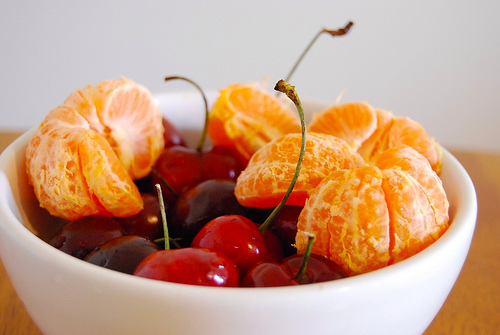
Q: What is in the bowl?
A: Fruit.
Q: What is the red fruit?
A: Cherries.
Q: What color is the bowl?
A: White.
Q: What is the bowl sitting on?
A: Table.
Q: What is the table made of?
A: Wood.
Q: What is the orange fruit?
A: Tangerine.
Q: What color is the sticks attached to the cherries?
A: Green.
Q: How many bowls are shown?
A: 1.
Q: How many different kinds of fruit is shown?
A: 2.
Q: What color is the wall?
A: White.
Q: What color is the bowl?
A: White.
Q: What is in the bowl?
A: Fruit.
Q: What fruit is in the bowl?
A: Oranges and cherries.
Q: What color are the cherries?
A: Red.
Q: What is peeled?
A: Oranges.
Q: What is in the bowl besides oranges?
A: Cherries.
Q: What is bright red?
A: Cherries.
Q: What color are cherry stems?
A: Green.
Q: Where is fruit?
A: In a bowl.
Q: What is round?
A: Bowl.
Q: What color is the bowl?
A: White.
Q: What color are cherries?
A: Red.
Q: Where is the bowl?
A: On table.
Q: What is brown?
A: The table.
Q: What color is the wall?
A: White.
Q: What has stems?
A: Cherries.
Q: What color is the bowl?
A: White.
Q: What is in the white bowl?
A: Fruit.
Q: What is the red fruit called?
A: Cherries.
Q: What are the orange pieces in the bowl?
A: Oranges.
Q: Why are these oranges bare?
A: They were peeled.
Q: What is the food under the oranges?
A: Cherries.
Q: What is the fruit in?
A: A bowl.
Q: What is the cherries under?
A: Oranges.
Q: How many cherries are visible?
A: 10.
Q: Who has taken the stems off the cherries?
A: No one.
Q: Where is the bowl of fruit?
A: On top of a table.